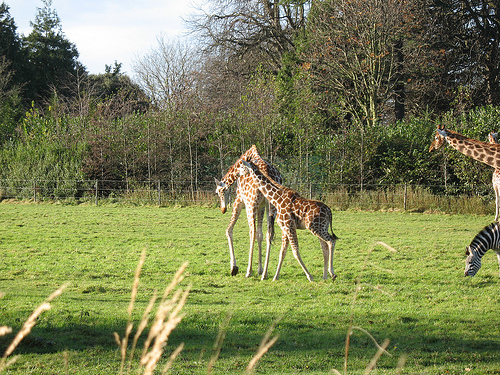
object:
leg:
[223, 202, 245, 278]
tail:
[326, 210, 342, 242]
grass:
[0, 189, 497, 372]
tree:
[116, 81, 131, 200]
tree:
[141, 95, 156, 197]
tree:
[315, 0, 423, 194]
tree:
[17, 0, 87, 143]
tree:
[271, 54, 326, 197]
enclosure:
[0, 177, 495, 208]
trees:
[0, 96, 90, 199]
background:
[0, 5, 496, 208]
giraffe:
[426, 123, 500, 224]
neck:
[214, 140, 262, 210]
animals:
[460, 219, 500, 281]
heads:
[235, 155, 254, 178]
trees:
[84, 105, 113, 192]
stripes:
[469, 230, 499, 254]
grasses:
[0, 234, 475, 371]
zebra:
[461, 219, 500, 281]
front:
[100, 168, 372, 238]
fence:
[10, 177, 218, 208]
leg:
[278, 218, 317, 285]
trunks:
[186, 141, 194, 201]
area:
[0, 187, 497, 373]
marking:
[214, 187, 219, 191]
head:
[212, 176, 235, 214]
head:
[462, 243, 484, 278]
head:
[427, 122, 449, 153]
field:
[6, 200, 484, 367]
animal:
[236, 154, 341, 284]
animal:
[212, 141, 284, 277]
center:
[174, 1, 371, 362]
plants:
[7, 232, 482, 366]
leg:
[271, 219, 290, 281]